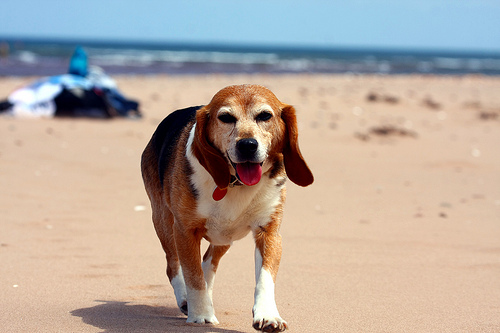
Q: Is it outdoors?
A: Yes, it is outdoors.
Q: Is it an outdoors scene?
A: Yes, it is outdoors.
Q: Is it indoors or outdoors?
A: It is outdoors.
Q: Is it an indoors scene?
A: No, it is outdoors.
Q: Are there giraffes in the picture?
A: No, there are no giraffes.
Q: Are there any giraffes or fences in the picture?
A: No, there are no giraffes or fences.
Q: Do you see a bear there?
A: No, there are no bears.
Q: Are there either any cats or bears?
A: No, there are no bears or cats.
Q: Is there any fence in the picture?
A: No, there are no fences.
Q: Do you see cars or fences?
A: No, there are no fences or cars.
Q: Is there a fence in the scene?
A: No, there are no fences.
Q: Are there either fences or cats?
A: No, there are no fences or cats.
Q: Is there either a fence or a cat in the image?
A: No, there are no fences or cats.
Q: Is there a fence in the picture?
A: No, there are no fences.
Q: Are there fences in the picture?
A: No, there are no fences.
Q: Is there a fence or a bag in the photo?
A: No, there are no fences or bags.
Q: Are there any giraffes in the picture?
A: No, there are no giraffes.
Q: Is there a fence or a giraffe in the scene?
A: No, there are no giraffes or fences.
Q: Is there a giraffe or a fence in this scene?
A: No, there are no giraffes or fences.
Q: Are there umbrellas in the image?
A: No, there are no umbrellas.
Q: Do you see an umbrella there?
A: No, there are no umbrellas.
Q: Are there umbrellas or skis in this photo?
A: No, there are no umbrellas or skis.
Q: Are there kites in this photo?
A: No, there are no kites.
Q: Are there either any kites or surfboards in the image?
A: No, there are no kites or surfboards.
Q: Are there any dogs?
A: Yes, there is a dog.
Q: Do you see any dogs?
A: Yes, there is a dog.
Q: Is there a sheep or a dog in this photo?
A: Yes, there is a dog.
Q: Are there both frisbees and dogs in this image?
A: No, there is a dog but no frisbees.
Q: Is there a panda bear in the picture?
A: No, there are no panda bears.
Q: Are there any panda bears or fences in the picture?
A: No, there are no panda bears or fences.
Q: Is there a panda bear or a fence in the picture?
A: No, there are no panda bears or fences.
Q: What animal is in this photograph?
A: The animal is a dog.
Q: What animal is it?
A: The animal is a dog.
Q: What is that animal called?
A: That is a dog.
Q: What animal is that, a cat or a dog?
A: That is a dog.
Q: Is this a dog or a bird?
A: This is a dog.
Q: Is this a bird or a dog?
A: This is a dog.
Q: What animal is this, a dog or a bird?
A: This is a dog.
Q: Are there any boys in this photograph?
A: No, there are no boys.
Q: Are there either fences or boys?
A: No, there are no boys or fences.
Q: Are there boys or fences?
A: No, there are no boys or fences.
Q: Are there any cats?
A: No, there are no cats.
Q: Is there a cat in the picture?
A: No, there are no cats.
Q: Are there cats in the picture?
A: No, there are no cats.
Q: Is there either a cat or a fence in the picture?
A: No, there are no cats or fences.